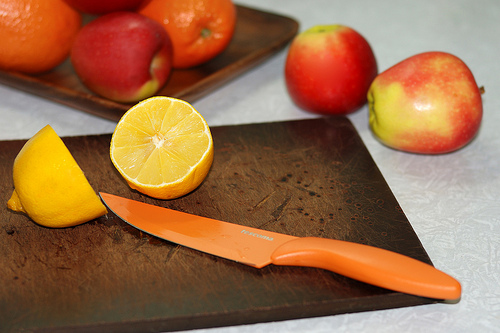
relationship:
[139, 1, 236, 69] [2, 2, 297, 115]
orange on top of cutting board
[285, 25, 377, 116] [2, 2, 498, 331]
apple on top of table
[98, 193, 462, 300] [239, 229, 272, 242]
knife has writting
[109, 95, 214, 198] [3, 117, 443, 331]
lemon on top of cutting board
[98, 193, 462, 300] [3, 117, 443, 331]
knife on top of cutting board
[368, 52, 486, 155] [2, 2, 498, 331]
apple on top of table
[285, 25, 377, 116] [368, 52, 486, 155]
apple next to apple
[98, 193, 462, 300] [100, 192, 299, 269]
knife has blade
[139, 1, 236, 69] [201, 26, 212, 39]
orange has end